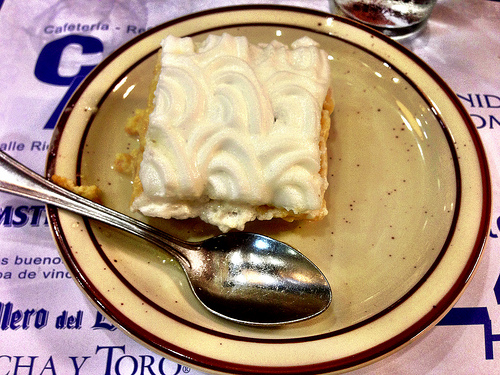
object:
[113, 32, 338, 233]
pie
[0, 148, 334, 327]
spoon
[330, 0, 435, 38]
glass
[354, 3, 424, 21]
water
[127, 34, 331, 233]
frosting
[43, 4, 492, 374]
plate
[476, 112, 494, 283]
rim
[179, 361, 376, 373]
rim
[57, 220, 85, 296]
rim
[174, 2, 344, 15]
rim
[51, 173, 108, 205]
piece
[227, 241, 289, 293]
light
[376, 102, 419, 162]
specks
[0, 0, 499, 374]
mat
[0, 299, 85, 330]
writing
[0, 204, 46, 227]
writing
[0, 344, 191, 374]
writing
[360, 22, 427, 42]
base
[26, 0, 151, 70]
water ring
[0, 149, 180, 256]
handle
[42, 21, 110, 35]
writing